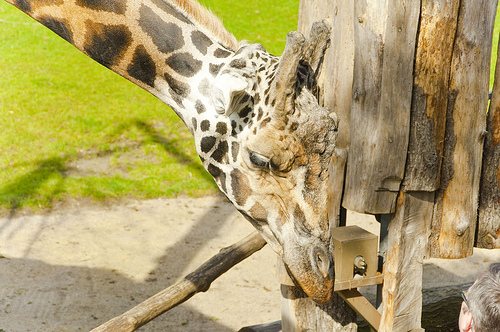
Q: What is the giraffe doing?
A: Looking at a person.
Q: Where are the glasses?
A: On the man's face.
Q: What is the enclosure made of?
A: Wood.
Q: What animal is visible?
A: Giraffe.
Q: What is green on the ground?
A: Grass.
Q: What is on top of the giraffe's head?
A: Ossicones.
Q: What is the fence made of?
A: Wood.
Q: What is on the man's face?
A: Glasses.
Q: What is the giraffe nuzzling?
A: Fence.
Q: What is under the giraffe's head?
A: Stick.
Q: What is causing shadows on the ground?
A: Sunshine.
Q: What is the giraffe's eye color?
A: Black.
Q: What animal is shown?
A: Giraffe.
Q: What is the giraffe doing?
A: Bending down.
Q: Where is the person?
A: Bottom right.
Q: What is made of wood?
A: Fence.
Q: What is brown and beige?
A: Giraffe.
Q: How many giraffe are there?
A: One.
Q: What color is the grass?
A: Green.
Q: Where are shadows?
A: On the ground.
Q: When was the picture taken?
A: Daytime.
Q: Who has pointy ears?
A: The giraffe.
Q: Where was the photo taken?
A: Near grass.